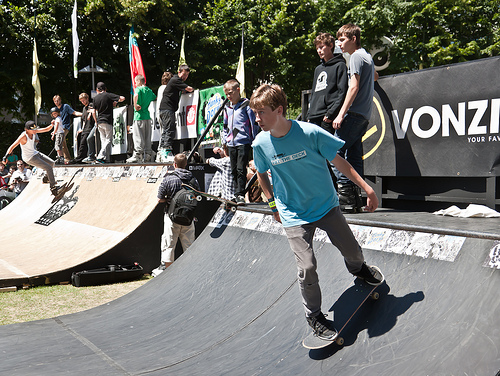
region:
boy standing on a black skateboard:
[232, 68, 392, 363]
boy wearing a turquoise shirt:
[231, 34, 398, 353]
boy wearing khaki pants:
[220, 53, 402, 370]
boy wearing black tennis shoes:
[224, 76, 404, 348]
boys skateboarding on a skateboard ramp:
[232, 75, 498, 356]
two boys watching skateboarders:
[289, 17, 411, 201]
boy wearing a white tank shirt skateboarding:
[5, 103, 84, 214]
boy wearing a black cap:
[10, 107, 93, 222]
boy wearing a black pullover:
[305, 21, 354, 141]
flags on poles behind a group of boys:
[11, 3, 246, 133]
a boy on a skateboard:
[235, 79, 398, 353]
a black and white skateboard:
[297, 263, 387, 357]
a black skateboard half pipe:
[4, 205, 492, 374]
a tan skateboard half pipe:
[0, 152, 162, 292]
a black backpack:
[166, 184, 201, 226]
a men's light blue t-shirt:
[242, 126, 354, 230]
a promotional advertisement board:
[355, 60, 498, 187]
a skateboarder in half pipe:
[1, 112, 78, 202]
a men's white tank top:
[16, 127, 37, 164]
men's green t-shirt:
[127, 86, 152, 120]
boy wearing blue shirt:
[198, 116, 348, 221]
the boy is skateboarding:
[238, 76, 395, 373]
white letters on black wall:
[380, 85, 493, 180]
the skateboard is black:
[261, 245, 407, 360]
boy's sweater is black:
[287, 46, 348, 114]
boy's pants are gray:
[262, 202, 413, 317]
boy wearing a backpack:
[166, 172, 206, 222]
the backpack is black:
[155, 175, 206, 231]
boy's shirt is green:
[127, 86, 162, 116]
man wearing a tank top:
[12, 128, 50, 165]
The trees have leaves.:
[145, 2, 317, 54]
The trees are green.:
[153, 2, 294, 55]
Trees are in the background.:
[162, 4, 285, 55]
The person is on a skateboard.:
[212, 71, 409, 357]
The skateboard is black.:
[227, 76, 408, 364]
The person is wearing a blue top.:
[225, 84, 357, 229]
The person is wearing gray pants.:
[268, 198, 403, 343]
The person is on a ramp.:
[102, 69, 498, 374]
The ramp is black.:
[181, 272, 285, 360]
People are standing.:
[30, 61, 205, 173]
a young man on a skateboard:
[239, 84, 384, 354]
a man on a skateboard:
[3, 121, 70, 203]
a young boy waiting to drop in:
[180, 81, 250, 210]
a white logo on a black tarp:
[388, 99, 498, 151]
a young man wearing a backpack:
[161, 155, 198, 278]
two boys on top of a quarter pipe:
[307, 19, 371, 214]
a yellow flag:
[31, 41, 45, 116]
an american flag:
[126, 29, 145, 87]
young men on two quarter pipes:
[2, 27, 473, 372]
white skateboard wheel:
[196, 193, 202, 200]